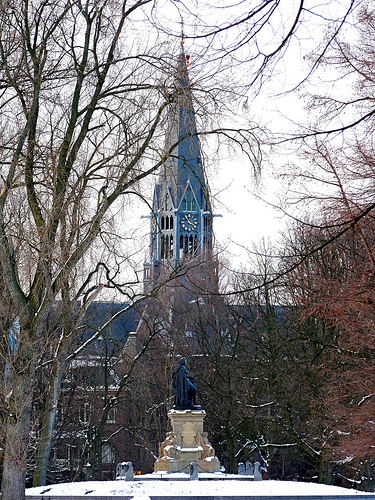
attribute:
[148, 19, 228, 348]
building — far, close, white, tall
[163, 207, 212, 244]
clock — gold, black, close, attached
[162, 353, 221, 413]
statue — large, black, water fountain, close, small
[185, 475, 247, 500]
snow — white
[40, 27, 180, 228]
tree — bare, thin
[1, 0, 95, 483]
trees — leafless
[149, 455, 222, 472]
base — tan